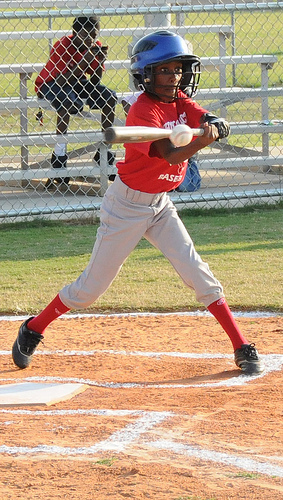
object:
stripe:
[0, 345, 283, 370]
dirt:
[0, 314, 283, 498]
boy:
[34, 14, 115, 180]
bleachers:
[0, 5, 281, 193]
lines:
[170, 434, 283, 498]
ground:
[0, 0, 283, 165]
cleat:
[234, 340, 261, 374]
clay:
[0, 305, 283, 498]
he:
[12, 27, 261, 374]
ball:
[169, 124, 192, 148]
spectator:
[34, 12, 116, 192]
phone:
[84, 44, 108, 59]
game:
[94, 42, 111, 63]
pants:
[57, 166, 226, 310]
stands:
[1, 20, 279, 188]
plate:
[0, 375, 88, 412]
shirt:
[116, 84, 211, 195]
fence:
[0, 0, 282, 222]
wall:
[0, 0, 283, 194]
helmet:
[129, 29, 202, 101]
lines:
[0, 299, 281, 500]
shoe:
[234, 341, 263, 376]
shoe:
[11, 314, 43, 369]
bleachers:
[208, 38, 280, 87]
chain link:
[0, 0, 283, 208]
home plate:
[0, 370, 94, 413]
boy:
[13, 34, 264, 375]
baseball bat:
[104, 125, 216, 150]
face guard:
[142, 56, 203, 100]